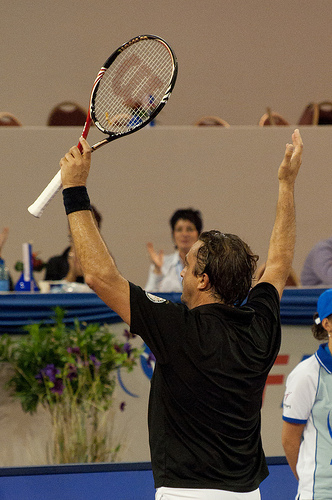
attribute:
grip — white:
[20, 167, 63, 220]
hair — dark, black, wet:
[191, 230, 258, 305]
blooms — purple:
[23, 334, 137, 392]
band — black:
[63, 186, 90, 217]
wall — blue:
[0, 454, 297, 499]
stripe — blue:
[282, 414, 307, 429]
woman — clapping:
[135, 205, 206, 292]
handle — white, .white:
[28, 174, 71, 215]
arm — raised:
[238, 122, 305, 315]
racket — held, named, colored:
[29, 36, 176, 220]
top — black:
[121, 277, 272, 494]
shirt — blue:
[279, 339, 331, 499]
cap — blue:
[310, 286, 331, 315]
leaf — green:
[101, 335, 112, 345]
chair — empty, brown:
[44, 101, 93, 129]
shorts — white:
[151, 488, 265, 499]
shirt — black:
[117, 275, 277, 496]